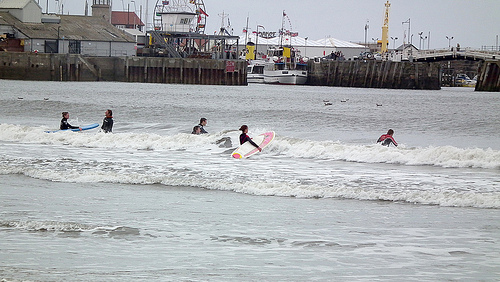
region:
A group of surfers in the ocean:
[40, 105, 417, 170]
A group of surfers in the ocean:
[37, 101, 423, 163]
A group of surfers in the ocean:
[38, 101, 418, 162]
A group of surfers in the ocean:
[49, 104, 423, 168]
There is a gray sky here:
[451, 8, 463, 27]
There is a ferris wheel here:
[152, 2, 215, 83]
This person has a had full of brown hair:
[106, 107, 118, 137]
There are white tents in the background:
[305, 21, 325, 60]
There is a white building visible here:
[70, 29, 89, 69]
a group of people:
[30, 73, 427, 173]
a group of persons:
[42, 82, 437, 182]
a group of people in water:
[31, 84, 474, 196]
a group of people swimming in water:
[6, 47, 471, 218]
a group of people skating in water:
[19, 67, 496, 221]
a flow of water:
[102, 135, 449, 221]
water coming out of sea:
[43, 205, 349, 262]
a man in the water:
[367, 113, 420, 162]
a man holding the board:
[215, 115, 262, 165]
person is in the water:
[370, 122, 405, 178]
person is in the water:
[229, 125, 271, 175]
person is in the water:
[187, 122, 209, 148]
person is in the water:
[96, 105, 124, 142]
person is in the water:
[48, 102, 84, 137]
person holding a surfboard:
[237, 120, 272, 163]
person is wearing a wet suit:
[95, 105, 125, 145]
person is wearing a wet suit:
[60, 111, 71, 123]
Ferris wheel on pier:
[151, 0, 215, 37]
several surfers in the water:
[52, 104, 445, 167]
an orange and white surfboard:
[230, 130, 278, 162]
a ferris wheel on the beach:
[141, 0, 218, 38]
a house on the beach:
[0, 1, 154, 63]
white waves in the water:
[2, 116, 496, 214]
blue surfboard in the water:
[62, 119, 104, 136]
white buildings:
[230, 30, 357, 57]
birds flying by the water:
[318, 90, 388, 114]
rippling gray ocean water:
[1, 87, 495, 279]